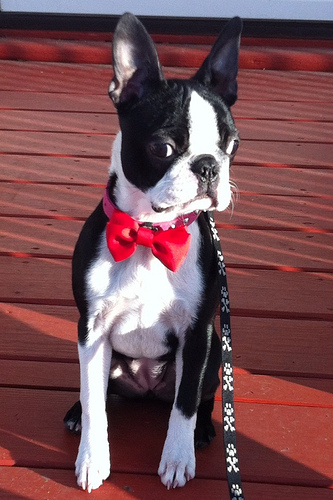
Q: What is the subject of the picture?
A: Dog.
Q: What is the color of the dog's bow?
A: Red.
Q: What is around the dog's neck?
A: Collar.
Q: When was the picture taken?
A: Daytime.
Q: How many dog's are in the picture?
A: One.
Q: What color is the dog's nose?
A: Black.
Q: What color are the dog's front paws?
A: White.